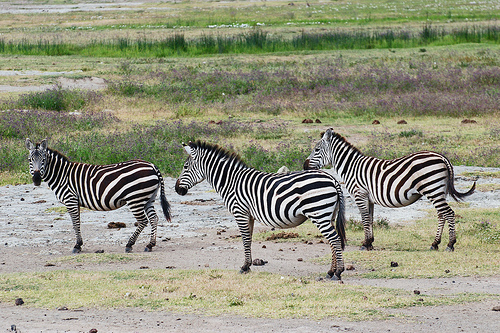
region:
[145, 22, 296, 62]
the grass is green in colour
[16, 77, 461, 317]
three wild zebras are standing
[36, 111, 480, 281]
the zebras are white and black in colour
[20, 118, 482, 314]
the colours are stripped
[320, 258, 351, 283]
the hooves are black in colour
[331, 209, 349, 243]
the tails are black in colour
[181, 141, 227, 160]
the mane is black in colour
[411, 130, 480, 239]
the tail is curved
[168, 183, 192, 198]
the mouth is black in colour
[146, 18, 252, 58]
the reeds are tall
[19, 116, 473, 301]
Zebras in a line.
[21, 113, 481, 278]
There are three zebras.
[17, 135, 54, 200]
One zebra looking at the camera.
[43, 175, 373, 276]
The dirt is dry.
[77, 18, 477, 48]
The grass is green.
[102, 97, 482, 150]
Some of the grass is brown.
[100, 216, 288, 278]
Dark clumps on the ground.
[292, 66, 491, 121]
Purple flowers on the ground.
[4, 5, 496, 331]
Taken in the wild.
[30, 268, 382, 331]
Dry grass patch in the dirt.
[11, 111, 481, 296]
three zebras on a field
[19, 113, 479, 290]
zebras facing right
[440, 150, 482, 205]
a tail is curved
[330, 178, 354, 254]
long tail of zebra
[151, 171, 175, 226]
long tail of zebra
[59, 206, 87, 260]
front legs of zebra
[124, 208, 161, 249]
back legs of zebra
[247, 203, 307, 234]
belly of zebra is bulky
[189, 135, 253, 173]
mane of zebra over the neck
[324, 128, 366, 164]
mane of zebra over the neck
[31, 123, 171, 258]
BLACK AND WHITE ZEBRA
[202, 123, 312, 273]
BLACK AND WHITE ZEBRA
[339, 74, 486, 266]
BLACK AND WHITE ZEBRA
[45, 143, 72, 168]
THICK MANE ON ZEBRA'S NECK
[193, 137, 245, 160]
THICK MANE ON ZEBRA'S NECK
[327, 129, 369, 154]
THICK MANE ON ZEBRA'S NECK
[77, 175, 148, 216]
BLACK AND WHITE STRIPES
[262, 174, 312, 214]
BLACK AND WHITE STRIPES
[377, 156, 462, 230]
BLACK AND WHITE STRIPES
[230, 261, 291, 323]
GRASS GROWING ON GROUND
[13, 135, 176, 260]
zebra in front looking at camera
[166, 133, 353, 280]
second zebra is looking ahead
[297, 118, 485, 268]
third zebra is looking ahead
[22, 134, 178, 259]
first zebra is black and white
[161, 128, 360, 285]
second zebra is black and white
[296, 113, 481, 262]
third zebra is black and white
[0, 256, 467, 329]
patch of grass to the right of the zebras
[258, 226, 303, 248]
small pile of mud on ground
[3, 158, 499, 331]
ground under zebras mostly dirt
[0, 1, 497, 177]
ground behind zebra is grass